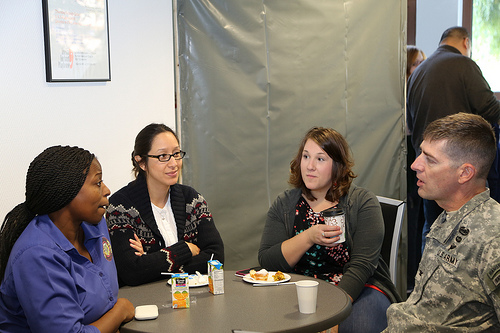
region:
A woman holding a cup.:
[259, 124, 397, 331]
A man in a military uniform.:
[382, 110, 498, 330]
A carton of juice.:
[206, 253, 225, 295]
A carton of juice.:
[160, 270, 190, 307]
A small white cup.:
[291, 278, 319, 313]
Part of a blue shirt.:
[30, 256, 47, 301]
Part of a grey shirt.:
[354, 223, 369, 253]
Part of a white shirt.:
[160, 214, 174, 236]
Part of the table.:
[241, 300, 263, 325]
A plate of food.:
[242, 267, 289, 285]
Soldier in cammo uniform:
[350, 100, 499, 332]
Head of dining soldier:
[408, 108, 499, 202]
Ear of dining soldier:
[453, 161, 478, 186]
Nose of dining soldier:
[408, 152, 422, 173]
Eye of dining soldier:
[421, 152, 441, 167]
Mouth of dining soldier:
[414, 177, 426, 186]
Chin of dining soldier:
[411, 187, 431, 199]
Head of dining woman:
[285, 125, 362, 200]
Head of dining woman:
[126, 119, 187, 190]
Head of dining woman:
[27, 143, 110, 226]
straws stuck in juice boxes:
[162, 246, 241, 305]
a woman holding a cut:
[269, 178, 364, 256]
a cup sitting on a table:
[286, 266, 321, 321]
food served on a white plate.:
[246, 258, 291, 294]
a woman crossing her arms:
[126, 195, 231, 270]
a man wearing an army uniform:
[378, 196, 498, 331]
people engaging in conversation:
[29, 146, 498, 269]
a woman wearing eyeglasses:
[129, 139, 212, 184]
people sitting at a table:
[48, 140, 495, 296]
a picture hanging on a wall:
[18, 5, 144, 112]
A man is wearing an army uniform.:
[386, 112, 498, 329]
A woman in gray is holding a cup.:
[259, 127, 397, 328]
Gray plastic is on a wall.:
[176, 0, 408, 299]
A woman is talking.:
[0, 146, 125, 331]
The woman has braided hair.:
[0, 145, 97, 254]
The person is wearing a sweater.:
[108, 177, 225, 287]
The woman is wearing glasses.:
[131, 122, 186, 184]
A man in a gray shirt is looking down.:
[407, 28, 494, 153]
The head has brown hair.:
[288, 125, 358, 202]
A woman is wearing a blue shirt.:
[0, 213, 118, 328]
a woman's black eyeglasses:
[137, 148, 192, 160]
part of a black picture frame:
[42, 1, 114, 87]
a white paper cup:
[292, 275, 320, 315]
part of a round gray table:
[122, 263, 350, 331]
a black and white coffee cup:
[322, 205, 347, 245]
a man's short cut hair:
[422, 109, 496, 180]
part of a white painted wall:
[109, 2, 179, 121]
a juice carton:
[172, 273, 191, 308]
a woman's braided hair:
[0, 145, 91, 272]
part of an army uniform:
[378, 188, 498, 331]